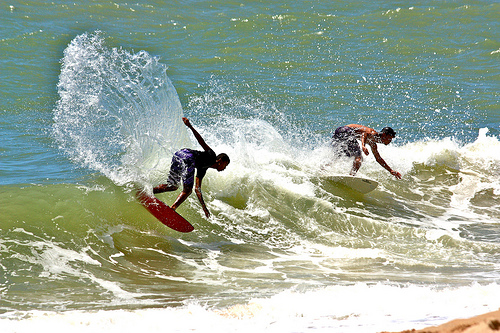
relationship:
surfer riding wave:
[147, 116, 231, 219] [2, 129, 500, 289]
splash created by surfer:
[46, 28, 196, 200] [147, 116, 231, 219]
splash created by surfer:
[190, 76, 333, 179] [314, 120, 405, 188]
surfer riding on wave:
[147, 116, 231, 219] [2, 129, 500, 289]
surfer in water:
[147, 116, 231, 219] [1, 3, 500, 332]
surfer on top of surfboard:
[147, 116, 231, 219] [123, 178, 197, 235]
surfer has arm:
[147, 116, 231, 219] [180, 114, 217, 155]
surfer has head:
[147, 116, 231, 219] [215, 151, 231, 174]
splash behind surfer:
[46, 28, 196, 200] [147, 116, 231, 219]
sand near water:
[379, 307, 499, 333] [1, 3, 500, 332]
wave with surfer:
[2, 129, 500, 289] [147, 116, 231, 219]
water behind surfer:
[1, 3, 500, 332] [147, 116, 231, 219]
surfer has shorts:
[314, 120, 405, 188] [333, 127, 363, 160]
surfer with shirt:
[147, 116, 231, 219] [186, 142, 214, 180]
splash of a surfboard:
[46, 28, 196, 200] [123, 178, 197, 235]